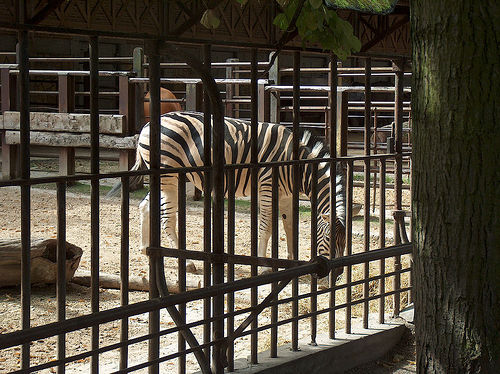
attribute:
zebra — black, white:
[83, 75, 360, 277]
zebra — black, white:
[123, 115, 358, 277]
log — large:
[419, 67, 499, 287]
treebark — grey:
[412, 2, 499, 371]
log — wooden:
[73, 255, 319, 312]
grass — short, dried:
[365, 243, 408, 298]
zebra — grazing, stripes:
[111, 109, 353, 283]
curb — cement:
[301, 325, 398, 371]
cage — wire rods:
[10, 45, 423, 371]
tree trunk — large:
[399, 4, 496, 372]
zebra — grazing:
[95, 136, 349, 304]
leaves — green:
[262, 12, 370, 61]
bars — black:
[0, 7, 405, 334]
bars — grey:
[8, 5, 420, 372]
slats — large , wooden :
[2, 104, 151, 154]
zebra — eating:
[115, 104, 368, 285]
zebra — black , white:
[125, 109, 355, 296]